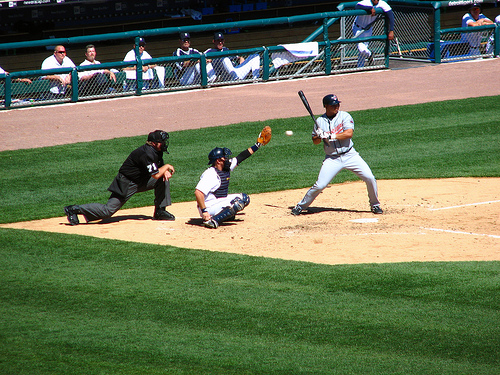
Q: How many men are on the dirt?
A: Three.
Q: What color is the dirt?
A: Brown.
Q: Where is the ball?
A: In the air.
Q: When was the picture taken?
A: Daytime.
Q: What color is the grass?
A: Green.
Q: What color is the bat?
A: Black.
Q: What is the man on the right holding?
A: A baseball bat.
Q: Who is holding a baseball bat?
A: The man on the right.